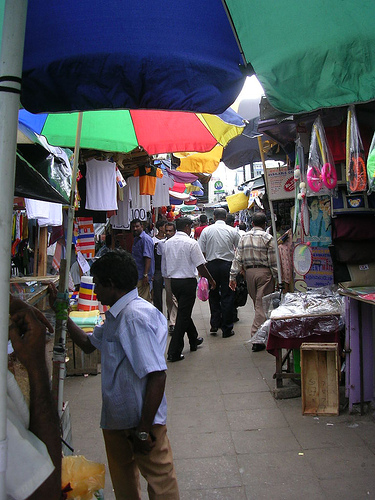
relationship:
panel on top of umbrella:
[130, 108, 214, 157] [15, 105, 247, 160]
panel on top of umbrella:
[44, 111, 139, 155] [15, 105, 247, 160]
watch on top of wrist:
[134, 430, 151, 442] [135, 427, 155, 441]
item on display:
[306, 115, 342, 196] [256, 107, 373, 213]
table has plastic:
[268, 286, 344, 325] [269, 285, 348, 336]